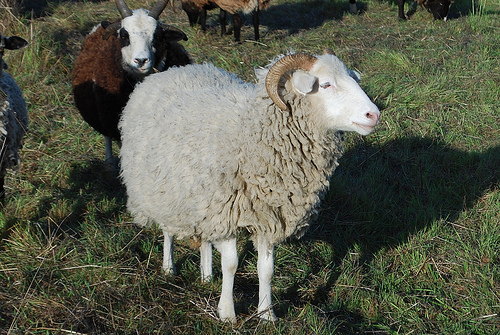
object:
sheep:
[115, 51, 379, 324]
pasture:
[2, 1, 500, 329]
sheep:
[66, 0, 191, 168]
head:
[264, 50, 385, 131]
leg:
[213, 239, 238, 324]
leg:
[254, 230, 279, 323]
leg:
[158, 230, 175, 275]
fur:
[134, 72, 321, 226]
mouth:
[353, 118, 378, 135]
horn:
[263, 54, 316, 111]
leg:
[196, 242, 216, 283]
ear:
[283, 68, 317, 95]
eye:
[318, 81, 332, 91]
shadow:
[300, 129, 500, 304]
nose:
[364, 104, 382, 120]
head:
[103, 8, 181, 77]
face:
[311, 49, 380, 136]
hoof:
[218, 312, 236, 323]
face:
[115, 13, 162, 69]